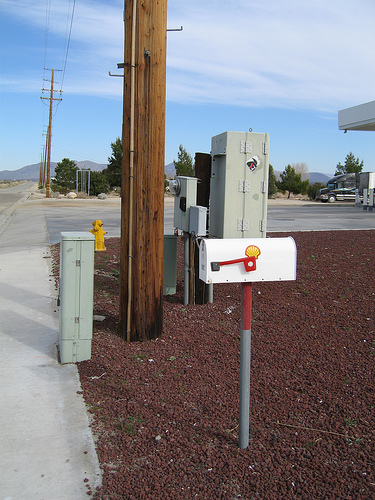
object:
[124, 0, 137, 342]
lining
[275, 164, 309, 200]
tree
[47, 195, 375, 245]
parking lot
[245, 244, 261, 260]
shell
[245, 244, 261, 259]
symbol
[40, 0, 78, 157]
wires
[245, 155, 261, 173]
sticker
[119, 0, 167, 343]
pole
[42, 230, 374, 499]
brown gravel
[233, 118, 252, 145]
ground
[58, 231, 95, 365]
box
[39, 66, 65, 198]
poles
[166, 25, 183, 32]
hook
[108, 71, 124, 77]
hook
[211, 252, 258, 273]
flag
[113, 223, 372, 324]
gravel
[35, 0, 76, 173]
power lines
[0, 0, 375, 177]
cloud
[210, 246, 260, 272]
red sign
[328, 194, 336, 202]
wheel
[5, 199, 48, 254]
entrance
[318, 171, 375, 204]
car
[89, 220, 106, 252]
fire hydrant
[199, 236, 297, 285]
box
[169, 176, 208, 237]
electric meter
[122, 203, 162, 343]
wooden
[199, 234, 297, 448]
stake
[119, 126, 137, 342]
long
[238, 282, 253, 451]
pole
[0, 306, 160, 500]
gravel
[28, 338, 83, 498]
road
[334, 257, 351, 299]
up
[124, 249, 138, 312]
brown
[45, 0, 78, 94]
poles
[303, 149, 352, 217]
lot